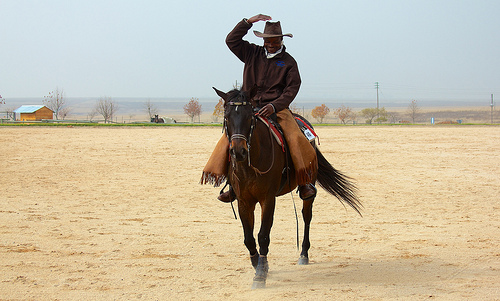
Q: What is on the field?
A: Sand.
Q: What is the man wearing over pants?
A: Leather chaps.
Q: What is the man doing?
A: Riding a horse.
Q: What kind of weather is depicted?
A: Sunny and clear.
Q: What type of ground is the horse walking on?
A: Dirt.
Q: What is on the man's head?
A: Hat.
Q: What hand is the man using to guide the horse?
A: Left.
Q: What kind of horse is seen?
A: Brown thoroughbred.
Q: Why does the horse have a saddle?
A: So the man can ride the horse.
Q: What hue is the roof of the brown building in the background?
A: Blue.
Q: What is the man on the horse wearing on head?
A: Hat.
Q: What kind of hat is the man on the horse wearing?
A: Cowboy.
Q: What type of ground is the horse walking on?
A: Sand.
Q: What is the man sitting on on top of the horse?
A: Saddle.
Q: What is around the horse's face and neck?
A: Reins.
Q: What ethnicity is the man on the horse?
A: Black.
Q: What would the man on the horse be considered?
A: A cowboy.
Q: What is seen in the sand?
A: Footprints.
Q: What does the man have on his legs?
A: Chaps.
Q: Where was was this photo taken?
A: A ranch.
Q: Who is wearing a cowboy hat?
A: The man.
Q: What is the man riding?
A: A horse.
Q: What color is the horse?
A: Brown.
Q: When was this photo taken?
A: Daytime.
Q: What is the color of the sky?
A: Blue.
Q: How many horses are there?
A: One.